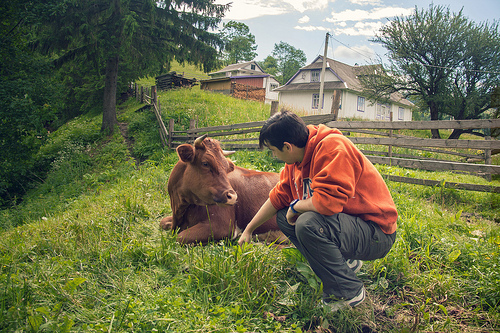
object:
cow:
[158, 131, 293, 244]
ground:
[0, 87, 499, 324]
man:
[236, 106, 398, 316]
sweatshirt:
[268, 122, 398, 234]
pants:
[276, 206, 397, 304]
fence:
[123, 81, 499, 193]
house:
[269, 54, 422, 121]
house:
[200, 60, 281, 104]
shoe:
[313, 282, 366, 312]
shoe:
[343, 258, 368, 277]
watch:
[287, 197, 302, 216]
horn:
[194, 132, 209, 146]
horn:
[221, 149, 238, 155]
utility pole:
[316, 31, 331, 114]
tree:
[351, 0, 499, 140]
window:
[310, 93, 325, 109]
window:
[357, 96, 367, 113]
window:
[308, 69, 320, 81]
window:
[396, 106, 405, 121]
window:
[250, 64, 256, 71]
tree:
[0, 0, 237, 140]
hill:
[34, 82, 162, 180]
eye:
[201, 162, 210, 166]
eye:
[229, 165, 234, 173]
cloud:
[326, 8, 421, 23]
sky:
[155, 0, 499, 96]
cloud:
[255, 0, 330, 20]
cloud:
[298, 14, 311, 28]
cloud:
[291, 24, 330, 34]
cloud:
[333, 42, 379, 58]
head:
[175, 132, 239, 206]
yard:
[123, 53, 500, 188]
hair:
[258, 108, 310, 152]